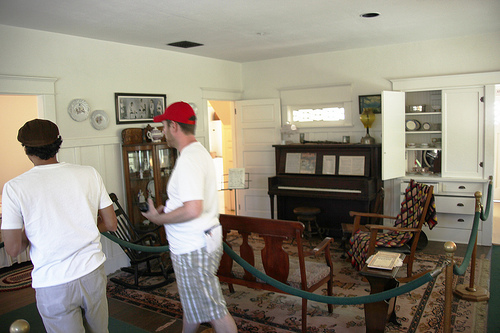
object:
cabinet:
[442, 88, 484, 182]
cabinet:
[381, 86, 484, 182]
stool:
[293, 206, 323, 240]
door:
[231, 96, 286, 218]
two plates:
[67, 98, 110, 131]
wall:
[0, 27, 243, 276]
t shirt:
[0, 160, 113, 290]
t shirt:
[161, 140, 223, 257]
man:
[140, 101, 239, 333]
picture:
[113, 91, 169, 124]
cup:
[359, 107, 376, 145]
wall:
[236, 29, 496, 255]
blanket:
[344, 183, 438, 276]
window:
[286, 105, 347, 122]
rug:
[108, 230, 489, 332]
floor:
[0, 231, 497, 332]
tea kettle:
[146, 127, 165, 143]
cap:
[153, 101, 197, 125]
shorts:
[168, 244, 230, 324]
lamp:
[359, 107, 376, 145]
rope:
[222, 242, 449, 305]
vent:
[166, 40, 204, 48]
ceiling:
[0, 0, 500, 62]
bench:
[217, 214, 336, 332]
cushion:
[228, 250, 330, 290]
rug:
[0, 260, 34, 293]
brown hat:
[17, 119, 60, 146]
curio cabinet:
[121, 124, 176, 248]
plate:
[90, 110, 111, 130]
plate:
[67, 98, 92, 123]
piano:
[266, 141, 381, 239]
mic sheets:
[285, 152, 302, 173]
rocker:
[346, 179, 436, 283]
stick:
[444, 254, 454, 331]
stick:
[469, 192, 479, 290]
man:
[0, 120, 121, 333]